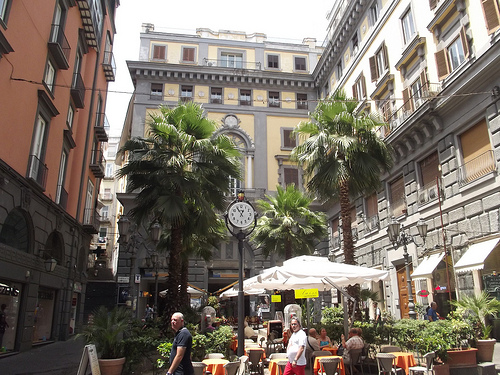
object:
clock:
[228, 202, 255, 228]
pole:
[238, 239, 246, 357]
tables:
[201, 359, 232, 375]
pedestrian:
[160, 302, 440, 375]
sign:
[294, 288, 319, 299]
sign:
[271, 295, 281, 303]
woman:
[317, 328, 331, 349]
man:
[164, 313, 195, 375]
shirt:
[170, 329, 195, 373]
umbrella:
[219, 255, 390, 300]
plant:
[74, 290, 499, 373]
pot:
[100, 356, 123, 375]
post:
[402, 240, 417, 320]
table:
[385, 352, 417, 366]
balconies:
[91, 112, 109, 143]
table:
[322, 347, 339, 355]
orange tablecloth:
[199, 358, 233, 375]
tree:
[108, 94, 386, 320]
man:
[283, 318, 308, 375]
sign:
[74, 343, 100, 374]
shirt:
[286, 329, 307, 366]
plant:
[417, 315, 444, 352]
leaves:
[183, 134, 243, 185]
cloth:
[390, 352, 420, 374]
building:
[2, 0, 500, 375]